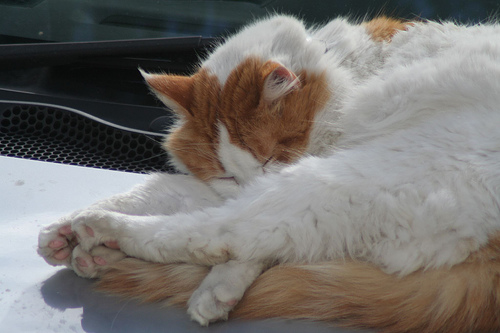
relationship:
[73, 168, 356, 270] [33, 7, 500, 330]
legs of cat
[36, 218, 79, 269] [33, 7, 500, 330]
paw of cat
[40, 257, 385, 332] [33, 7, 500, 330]
shadow of cat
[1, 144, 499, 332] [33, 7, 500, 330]
table behind cat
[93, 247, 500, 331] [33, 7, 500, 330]
tail of cat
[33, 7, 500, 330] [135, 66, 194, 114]
cat has ear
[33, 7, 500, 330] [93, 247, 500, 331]
cat has tail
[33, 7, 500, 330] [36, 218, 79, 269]
cat has paw